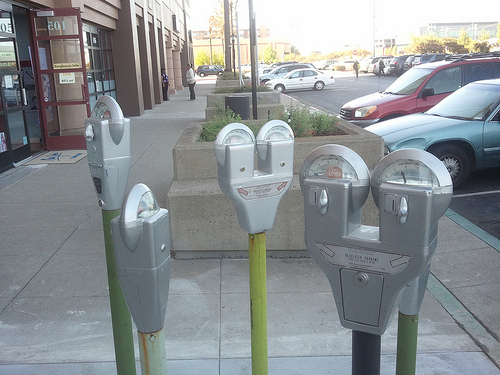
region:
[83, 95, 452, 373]
a group of parking meters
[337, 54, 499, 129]
the red van is parked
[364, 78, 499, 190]
the blue car is parked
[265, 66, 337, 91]
a white car is parked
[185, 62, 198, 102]
a woman wearing a white sweater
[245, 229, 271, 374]
the parking meter has a yellow pole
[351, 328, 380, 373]
the parking meter has a black pole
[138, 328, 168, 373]
the parking meter has a white pole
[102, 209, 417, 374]
two parking meters have green poles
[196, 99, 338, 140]
some plants growing in a planter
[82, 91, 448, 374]
five parking meters gathered in one area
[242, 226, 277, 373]
parking meter pole painted light green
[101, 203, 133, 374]
parking meter pole painted dark green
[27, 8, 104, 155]
red door is open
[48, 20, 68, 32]
number 105 on outside of red door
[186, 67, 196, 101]
man standing in the background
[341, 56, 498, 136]
red van parked in parking space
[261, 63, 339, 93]
white car parked in parking space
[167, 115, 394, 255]
concrete plant container and area to sit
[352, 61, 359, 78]
person walking to vehicle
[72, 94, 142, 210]
Large silver parking meter.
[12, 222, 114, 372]
Cracks in the sidewalk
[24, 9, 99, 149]
Wooden brown door with glass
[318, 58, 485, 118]
A burgundy colored car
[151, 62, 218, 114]
Two women talking on sidewalk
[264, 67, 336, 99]
Blue and white cars parked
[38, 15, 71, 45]
Company number 105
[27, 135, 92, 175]
Mat outside of company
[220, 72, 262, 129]
Trash can in the middle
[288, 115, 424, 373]
Double count parking meter.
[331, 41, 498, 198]
cars parked on a street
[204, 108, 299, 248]
parking meters on a post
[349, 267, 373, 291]
lock on a parking meter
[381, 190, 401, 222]
coin slot on a parking meter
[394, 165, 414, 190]
arrow in a parking meter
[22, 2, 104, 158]
door on a building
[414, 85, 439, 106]
side rear view mirror of a vehicle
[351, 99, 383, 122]
front headlight on a vehicle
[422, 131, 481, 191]
front wheel of a vehicle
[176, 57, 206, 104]
person with a white shirt standing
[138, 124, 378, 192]
A parking meter on the street.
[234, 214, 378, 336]
Pole of the parking meter.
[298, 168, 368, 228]
Slot for the money.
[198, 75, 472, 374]
Parking meters on the corner.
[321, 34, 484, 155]
Car parked on the road.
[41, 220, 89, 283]
Crack on the sidewalk.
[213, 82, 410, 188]
Bushes in the box.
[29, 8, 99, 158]
Door to a shop.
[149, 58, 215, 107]
People in the background.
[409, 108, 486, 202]
Wheel on the car.